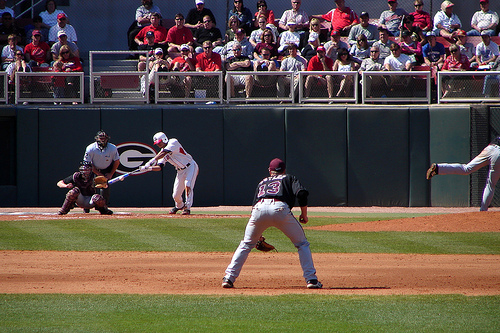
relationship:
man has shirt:
[24, 29, 48, 62] [26, 44, 50, 62]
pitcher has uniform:
[220, 157, 325, 290] [219, 174, 320, 282]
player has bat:
[152, 131, 201, 217] [105, 164, 147, 188]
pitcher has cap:
[220, 157, 325, 290] [266, 159, 288, 172]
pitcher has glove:
[220, 157, 325, 290] [253, 235, 278, 253]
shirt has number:
[256, 173, 309, 209] [268, 181, 281, 196]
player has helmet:
[152, 131, 201, 217] [152, 132, 171, 146]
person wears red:
[191, 40, 224, 104] [195, 51, 224, 77]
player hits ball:
[152, 131, 201, 217] [118, 176, 125, 182]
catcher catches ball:
[55, 161, 114, 215] [118, 176, 125, 182]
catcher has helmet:
[55, 161, 114, 215] [76, 159, 99, 171]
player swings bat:
[152, 131, 201, 217] [105, 164, 147, 188]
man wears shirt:
[24, 29, 48, 62] [26, 44, 50, 62]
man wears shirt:
[167, 13, 192, 44] [167, 24, 191, 45]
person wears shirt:
[191, 40, 224, 104] [197, 53, 220, 71]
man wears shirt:
[326, 0, 357, 27] [329, 9, 354, 30]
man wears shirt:
[309, 44, 333, 99] [310, 55, 331, 70]